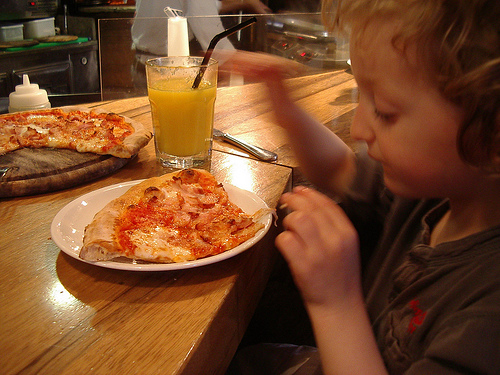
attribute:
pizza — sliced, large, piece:
[96, 170, 242, 256]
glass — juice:
[142, 52, 224, 181]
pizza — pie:
[1, 111, 141, 166]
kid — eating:
[338, 82, 499, 316]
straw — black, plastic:
[193, 24, 257, 87]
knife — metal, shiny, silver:
[214, 127, 281, 178]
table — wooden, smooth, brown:
[222, 77, 314, 194]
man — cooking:
[139, 1, 250, 82]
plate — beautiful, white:
[67, 186, 96, 269]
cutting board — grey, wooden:
[5, 155, 114, 197]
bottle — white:
[15, 68, 57, 113]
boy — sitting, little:
[273, 12, 500, 223]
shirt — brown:
[371, 235, 498, 358]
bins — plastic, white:
[4, 21, 74, 42]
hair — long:
[430, 16, 497, 134]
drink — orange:
[150, 70, 225, 154]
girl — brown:
[320, 36, 482, 214]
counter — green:
[18, 38, 101, 48]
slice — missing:
[15, 154, 99, 183]